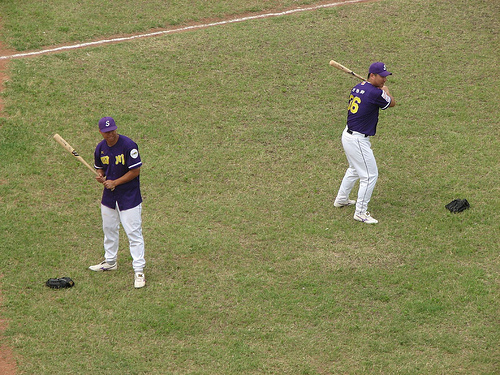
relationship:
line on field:
[123, 20, 199, 63] [205, 25, 305, 175]